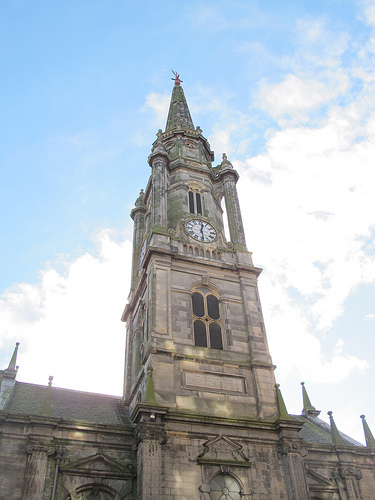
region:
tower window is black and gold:
[179, 273, 233, 360]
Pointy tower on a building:
[104, 54, 294, 427]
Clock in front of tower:
[175, 208, 223, 252]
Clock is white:
[181, 216, 220, 248]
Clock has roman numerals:
[179, 213, 220, 246]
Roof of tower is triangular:
[150, 63, 210, 132]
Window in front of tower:
[185, 271, 238, 354]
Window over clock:
[180, 171, 215, 214]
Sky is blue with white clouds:
[4, 4, 374, 365]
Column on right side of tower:
[216, 148, 259, 254]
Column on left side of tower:
[142, 126, 177, 234]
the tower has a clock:
[187, 219, 215, 246]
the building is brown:
[0, 72, 374, 498]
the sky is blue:
[1, 0, 373, 442]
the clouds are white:
[0, 0, 373, 445]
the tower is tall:
[127, 71, 287, 419]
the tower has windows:
[190, 291, 226, 353]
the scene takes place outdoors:
[0, 1, 372, 498]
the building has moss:
[139, 368, 297, 416]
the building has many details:
[0, 71, 374, 498]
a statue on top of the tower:
[169, 69, 182, 85]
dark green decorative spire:
[134, 354, 169, 414]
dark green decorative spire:
[267, 375, 295, 425]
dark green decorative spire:
[286, 372, 324, 417]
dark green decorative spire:
[314, 405, 350, 450]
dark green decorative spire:
[354, 410, 374, 455]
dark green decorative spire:
[1, 337, 28, 382]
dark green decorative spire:
[36, 364, 62, 424]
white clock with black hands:
[181, 211, 221, 245]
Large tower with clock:
[123, 48, 266, 438]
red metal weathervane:
[165, 60, 187, 95]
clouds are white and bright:
[11, 281, 116, 380]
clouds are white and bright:
[279, 300, 355, 399]